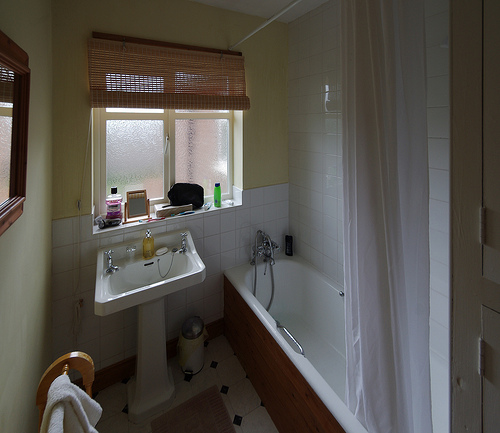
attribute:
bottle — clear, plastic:
[103, 183, 123, 220]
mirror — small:
[128, 199, 147, 214]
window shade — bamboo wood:
[79, 35, 251, 110]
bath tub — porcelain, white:
[218, 249, 415, 431]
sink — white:
[93, 226, 204, 314]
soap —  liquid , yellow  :
[139, 228, 156, 259]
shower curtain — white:
[336, 2, 433, 432]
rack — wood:
[29, 346, 100, 430]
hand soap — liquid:
[129, 221, 172, 263]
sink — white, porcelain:
[89, 228, 211, 415]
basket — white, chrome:
[179, 312, 211, 374]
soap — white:
[150, 244, 177, 258]